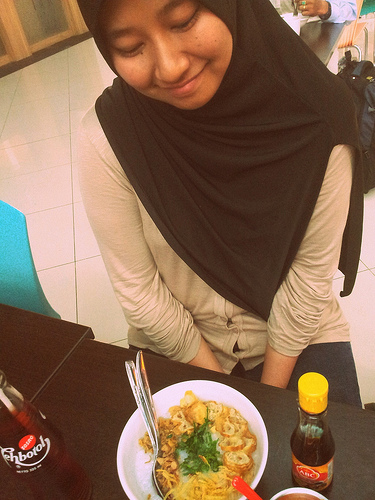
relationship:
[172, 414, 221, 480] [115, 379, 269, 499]
green garnish in bowl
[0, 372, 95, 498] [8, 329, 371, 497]
soda on table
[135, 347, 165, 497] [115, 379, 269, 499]
spoon on bowl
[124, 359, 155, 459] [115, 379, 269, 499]
spoon on bowl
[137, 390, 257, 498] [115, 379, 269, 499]
food in bowl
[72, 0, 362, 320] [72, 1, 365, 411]
burka is on girl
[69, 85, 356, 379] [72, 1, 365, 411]
shirt is on girl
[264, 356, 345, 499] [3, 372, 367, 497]
bottle is on table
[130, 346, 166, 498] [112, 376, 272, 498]
cuttler is on plate